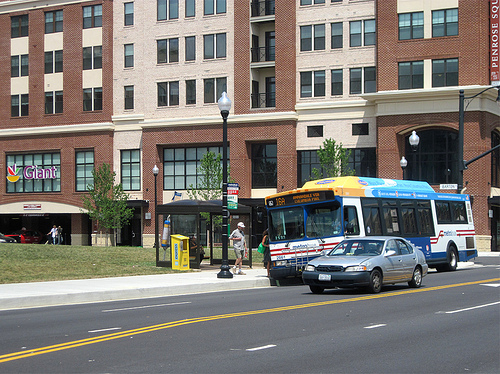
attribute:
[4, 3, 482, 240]
building — in the background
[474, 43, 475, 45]
text — white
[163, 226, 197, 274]
stand — yellow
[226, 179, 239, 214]
bus sign — multicolored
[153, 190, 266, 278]
bus stop — black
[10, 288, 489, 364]
street — black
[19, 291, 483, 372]
lines — dashed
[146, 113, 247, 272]
posts — black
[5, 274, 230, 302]
sidewalk — clean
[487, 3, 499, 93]
sign — red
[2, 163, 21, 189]
logo — colorful